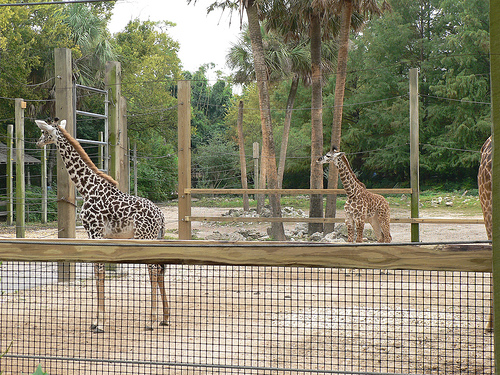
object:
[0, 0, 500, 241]
trees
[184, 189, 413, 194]
beam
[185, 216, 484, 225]
beam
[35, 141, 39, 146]
nose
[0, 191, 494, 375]
ground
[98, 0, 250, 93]
sky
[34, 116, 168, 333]
giraffe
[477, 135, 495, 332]
giraffe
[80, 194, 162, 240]
spots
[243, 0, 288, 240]
tree bark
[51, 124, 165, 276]
fur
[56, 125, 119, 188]
neck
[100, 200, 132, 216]
pattern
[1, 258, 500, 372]
fence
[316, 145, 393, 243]
giraffe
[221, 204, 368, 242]
rocks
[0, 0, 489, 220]
leaves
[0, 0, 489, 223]
dense vegetation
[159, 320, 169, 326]
hoof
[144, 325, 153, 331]
hoof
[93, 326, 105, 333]
hoof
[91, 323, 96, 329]
hoof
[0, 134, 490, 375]
field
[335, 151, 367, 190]
mane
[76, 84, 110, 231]
door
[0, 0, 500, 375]
exhibit